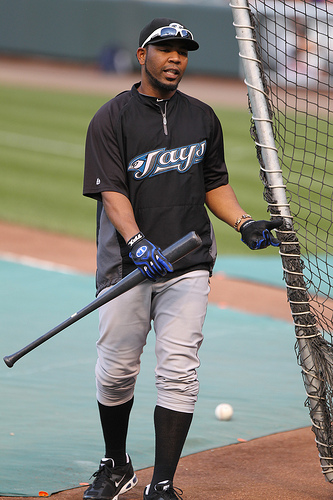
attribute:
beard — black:
[141, 67, 183, 92]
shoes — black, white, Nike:
[83, 454, 178, 499]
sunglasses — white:
[130, 25, 226, 59]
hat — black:
[137, 16, 198, 51]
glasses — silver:
[138, 24, 194, 40]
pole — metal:
[226, 4, 332, 373]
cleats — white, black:
[79, 449, 137, 497]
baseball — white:
[210, 400, 235, 423]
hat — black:
[132, 19, 200, 49]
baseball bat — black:
[0, 229, 208, 373]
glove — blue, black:
[126, 237, 176, 276]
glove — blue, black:
[242, 219, 281, 248]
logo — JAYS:
[128, 135, 215, 184]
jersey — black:
[131, 118, 234, 227]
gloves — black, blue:
[117, 214, 292, 278]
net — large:
[252, 13, 330, 491]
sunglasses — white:
[138, 24, 191, 53]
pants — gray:
[92, 257, 211, 417]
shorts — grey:
[91, 263, 210, 419]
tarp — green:
[3, 258, 309, 496]